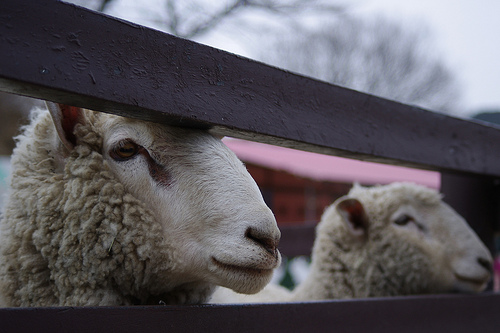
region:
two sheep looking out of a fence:
[14, 13, 498, 308]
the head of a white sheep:
[22, 99, 260, 301]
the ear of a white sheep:
[42, 86, 106, 160]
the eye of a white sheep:
[103, 135, 148, 171]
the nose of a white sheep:
[231, 215, 278, 245]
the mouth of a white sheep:
[217, 245, 285, 292]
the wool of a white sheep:
[32, 175, 126, 260]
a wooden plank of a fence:
[112, 1, 374, 156]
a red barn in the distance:
[235, 132, 320, 249]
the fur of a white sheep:
[187, 189, 229, 231]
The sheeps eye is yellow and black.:
[111, 133, 141, 163]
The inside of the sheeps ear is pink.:
[41, 100, 91, 142]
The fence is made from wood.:
[238, 77, 347, 131]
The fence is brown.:
[260, 78, 400, 143]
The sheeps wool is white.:
[21, 172, 109, 277]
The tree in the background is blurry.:
[306, 6, 419, 70]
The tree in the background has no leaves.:
[313, 19, 455, 72]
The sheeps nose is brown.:
[245, 220, 283, 254]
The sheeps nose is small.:
[243, 217, 283, 251]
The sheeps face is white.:
[53, 114, 318, 302]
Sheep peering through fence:
[19, 103, 291, 305]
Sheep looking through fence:
[319, 178, 492, 290]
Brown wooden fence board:
[2, 0, 499, 174]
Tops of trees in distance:
[98, 0, 465, 110]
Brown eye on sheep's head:
[111, 133, 141, 160]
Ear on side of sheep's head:
[331, 198, 369, 237]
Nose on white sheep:
[243, 218, 282, 255]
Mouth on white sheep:
[210, 250, 280, 280]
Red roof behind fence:
[231, 140, 443, 180]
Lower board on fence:
[1, 298, 498, 331]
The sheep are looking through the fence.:
[10, 6, 487, 295]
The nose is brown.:
[234, 218, 281, 259]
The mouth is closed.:
[197, 254, 287, 291]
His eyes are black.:
[97, 130, 150, 158]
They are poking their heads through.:
[18, 93, 495, 328]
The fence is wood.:
[8, 7, 498, 192]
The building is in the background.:
[220, 138, 447, 244]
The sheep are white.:
[0, 16, 472, 328]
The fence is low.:
[0, 9, 492, 330]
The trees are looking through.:
[107, 2, 498, 84]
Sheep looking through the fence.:
[13, 37, 473, 299]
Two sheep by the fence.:
[17, 55, 472, 322]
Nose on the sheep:
[188, 179, 308, 304]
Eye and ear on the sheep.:
[36, 92, 191, 228]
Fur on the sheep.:
[11, 108, 184, 315]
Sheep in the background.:
[291, 162, 497, 298]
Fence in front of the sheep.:
[218, 22, 492, 238]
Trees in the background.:
[286, 0, 487, 127]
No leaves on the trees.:
[278, 7, 499, 131]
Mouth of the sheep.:
[180, 242, 282, 301]